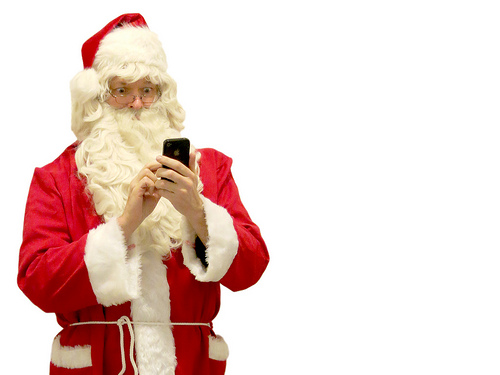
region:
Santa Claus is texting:
[75, 17, 222, 216]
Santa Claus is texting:
[77, 28, 213, 243]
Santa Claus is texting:
[51, 16, 212, 217]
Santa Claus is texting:
[60, 26, 220, 226]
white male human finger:
[151, 187, 173, 199]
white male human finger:
[151, 176, 177, 191]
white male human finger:
[155, 166, 182, 181]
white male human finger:
[155, 153, 192, 175]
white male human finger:
[188, 150, 198, 170]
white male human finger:
[132, 178, 154, 197]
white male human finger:
[131, 165, 156, 181]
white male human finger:
[148, 161, 163, 171]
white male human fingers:
[151, 153, 200, 202]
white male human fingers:
[129, 161, 166, 203]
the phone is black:
[154, 128, 197, 208]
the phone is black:
[144, 136, 206, 205]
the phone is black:
[155, 128, 208, 210]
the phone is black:
[157, 133, 202, 218]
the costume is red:
[22, 125, 251, 363]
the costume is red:
[32, 129, 260, 364]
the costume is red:
[27, 134, 263, 374]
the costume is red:
[27, 129, 279, 368]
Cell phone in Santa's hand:
[162, 137, 192, 171]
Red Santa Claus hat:
[79, 8, 163, 70]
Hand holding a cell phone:
[159, 153, 205, 243]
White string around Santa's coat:
[63, 314, 216, 373]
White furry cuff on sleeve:
[81, 221, 143, 305]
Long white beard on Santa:
[92, 107, 183, 244]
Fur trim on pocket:
[48, 333, 98, 365]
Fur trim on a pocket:
[199, 326, 231, 355]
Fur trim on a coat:
[136, 251, 183, 373]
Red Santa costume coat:
[22, 133, 270, 373]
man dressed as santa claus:
[25, 17, 277, 374]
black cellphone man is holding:
[155, 141, 185, 186]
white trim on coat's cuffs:
[83, 193, 239, 293]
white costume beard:
[72, 92, 183, 252]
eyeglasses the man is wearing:
[104, 82, 154, 103]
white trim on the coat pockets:
[50, 330, 225, 372]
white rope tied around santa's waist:
[70, 313, 223, 373]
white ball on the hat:
[70, 70, 97, 99]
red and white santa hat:
[73, 11, 165, 95]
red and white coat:
[27, 147, 263, 374]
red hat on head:
[76, 10, 163, 40]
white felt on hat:
[84, 24, 176, 69]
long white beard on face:
[111, 102, 181, 160]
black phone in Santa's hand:
[153, 134, 198, 176]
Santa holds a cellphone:
[7, 2, 279, 373]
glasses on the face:
[103, 82, 167, 109]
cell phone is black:
[157, 133, 199, 173]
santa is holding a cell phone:
[17, 12, 268, 373]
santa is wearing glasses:
[19, 11, 269, 372]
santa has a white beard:
[19, 10, 270, 374]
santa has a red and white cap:
[18, 10, 273, 374]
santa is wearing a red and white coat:
[16, 16, 271, 373]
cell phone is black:
[164, 136, 190, 183]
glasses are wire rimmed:
[105, 87, 162, 106]